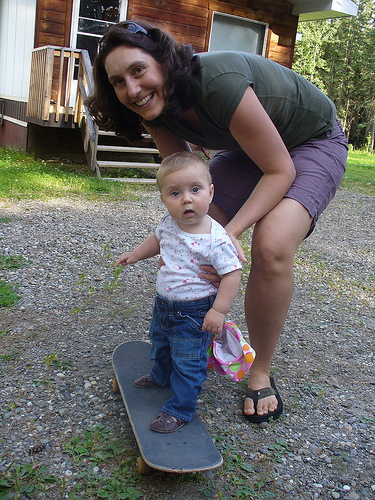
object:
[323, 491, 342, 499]
pebble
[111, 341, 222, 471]
skateboard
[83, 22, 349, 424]
woman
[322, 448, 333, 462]
pebble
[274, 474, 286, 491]
pebble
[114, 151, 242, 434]
baby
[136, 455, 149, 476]
wheel